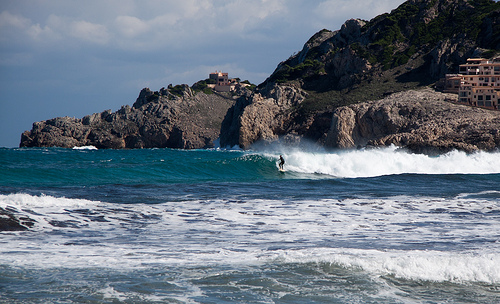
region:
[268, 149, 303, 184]
a man is surfing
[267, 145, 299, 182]
a man is surfing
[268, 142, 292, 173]
a man is surfing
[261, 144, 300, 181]
a man is surfing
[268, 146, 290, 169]
a man is surfing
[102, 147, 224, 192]
the water is blue-green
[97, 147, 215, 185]
the water is blue-green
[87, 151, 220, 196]
the water is blue-green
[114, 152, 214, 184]
the water is blue-green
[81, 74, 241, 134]
brown and rocky cliff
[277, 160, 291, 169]
man is on water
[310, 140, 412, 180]
white wave is crashing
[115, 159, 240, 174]
water is greenish blue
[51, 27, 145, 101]
blue and white sky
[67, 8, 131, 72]
puffy clouds in sky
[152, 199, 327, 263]
white foam on water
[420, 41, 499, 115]
grey building on shore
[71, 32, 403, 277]
ocean hitting the rocks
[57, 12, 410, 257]
ocean hitting the rocks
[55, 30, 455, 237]
ocean hitting the rocks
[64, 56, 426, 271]
ocean hitting the rocks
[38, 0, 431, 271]
ocean hitting the rocks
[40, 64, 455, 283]
ocean hitting the rocks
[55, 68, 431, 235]
ocean hitting the rocks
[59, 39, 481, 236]
ocean hitting the rocks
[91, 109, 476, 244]
ocean hitting the rocks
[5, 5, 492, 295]
a scene outside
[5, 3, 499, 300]
a scene during the day time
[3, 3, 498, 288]
a scene of a ocean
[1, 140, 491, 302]
a blue body of water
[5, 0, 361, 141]
a sky with some clouds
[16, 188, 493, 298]
a white form on water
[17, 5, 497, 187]
a rocky cliff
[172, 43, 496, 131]
some buildings in background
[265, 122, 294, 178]
a surfer in the water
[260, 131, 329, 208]
a person in the water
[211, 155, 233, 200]
this is a beautiful beach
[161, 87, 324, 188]
this is a large rock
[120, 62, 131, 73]
this is a cloud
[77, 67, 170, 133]
the cloud is white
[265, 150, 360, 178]
this is a large wave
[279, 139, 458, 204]
the wave is white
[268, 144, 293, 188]
this is a man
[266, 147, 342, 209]
this is a surfer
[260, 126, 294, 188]
this is a board